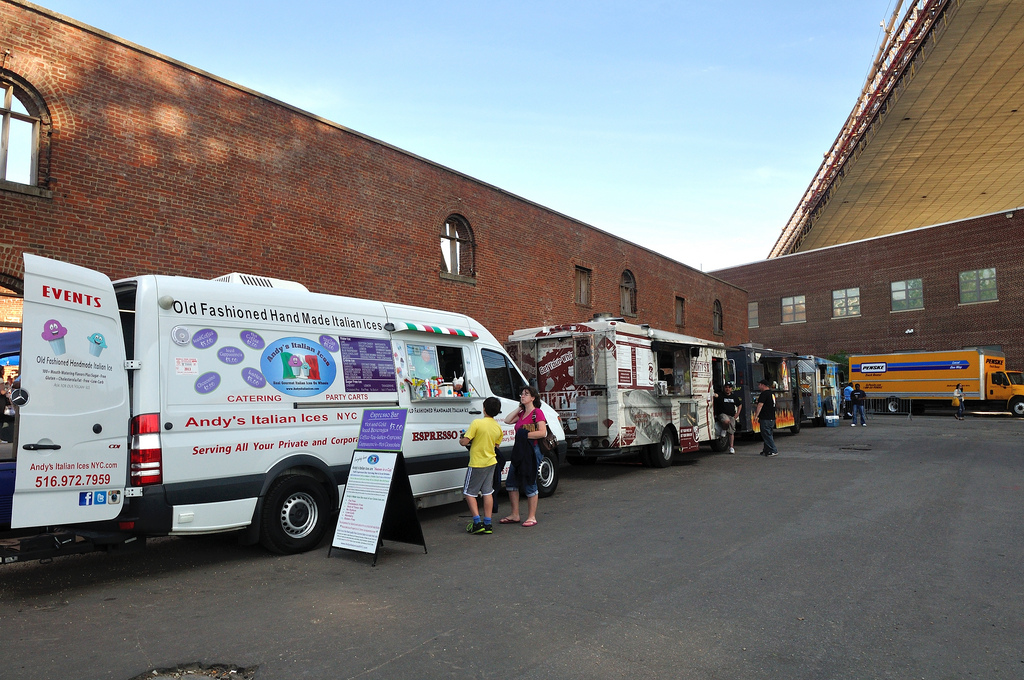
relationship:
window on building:
[438, 217, 471, 267] [11, 11, 981, 381]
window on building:
[438, 217, 476, 276] [11, 11, 981, 381]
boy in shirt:
[751, 363, 795, 461] [458, 396, 515, 481]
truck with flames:
[23, 214, 587, 582] [166, 323, 301, 391]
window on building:
[879, 269, 932, 313] [11, 11, 981, 381]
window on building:
[881, 273, 940, 312] [11, 11, 981, 381]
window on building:
[888, 279, 927, 311] [11, 11, 981, 381]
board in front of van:
[312, 404, 440, 575] [131, 264, 566, 554]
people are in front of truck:
[461, 376, 555, 519] [24, 275, 559, 536]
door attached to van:
[16, 247, 159, 582] [131, 264, 566, 554]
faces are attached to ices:
[262, 329, 332, 396] [262, 340, 355, 407]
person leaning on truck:
[703, 374, 781, 476] [552, 292, 797, 468]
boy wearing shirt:
[461, 396, 511, 543] [457, 419, 501, 465]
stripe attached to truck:
[846, 342, 974, 375] [841, 335, 1010, 418]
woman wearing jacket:
[503, 388, 560, 514] [513, 424, 546, 479]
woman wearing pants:
[500, 435, 561, 515] [502, 435, 546, 535]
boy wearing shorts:
[462, 396, 503, 535] [467, 448, 519, 501]